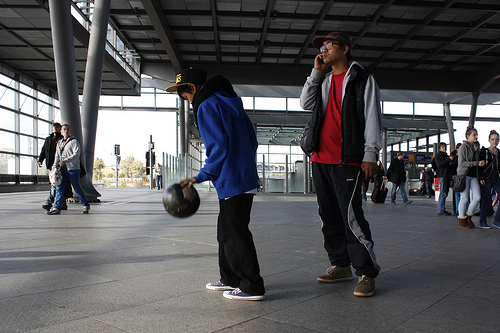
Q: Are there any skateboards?
A: No, there are no skateboards.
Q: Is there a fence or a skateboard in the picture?
A: No, there are no skateboards or fences.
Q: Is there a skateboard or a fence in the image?
A: No, there are no skateboards or fences.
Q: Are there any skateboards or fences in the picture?
A: No, there are no skateboards or fences.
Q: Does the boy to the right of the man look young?
A: Yes, the boy is young.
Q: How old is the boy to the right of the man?
A: The boy is young.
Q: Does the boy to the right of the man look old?
A: No, the boy is young.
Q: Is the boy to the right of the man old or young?
A: The boy is young.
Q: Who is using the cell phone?
A: The boy is using the cell phone.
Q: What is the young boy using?
A: The boy is using a mobile phone.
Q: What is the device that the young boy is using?
A: The device is a cell phone.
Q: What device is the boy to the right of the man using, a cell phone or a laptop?
A: The boy is using a cell phone.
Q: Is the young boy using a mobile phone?
A: Yes, the boy is using a mobile phone.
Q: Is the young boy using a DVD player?
A: No, the boy is using a mobile phone.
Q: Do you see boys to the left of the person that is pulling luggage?
A: Yes, there is a boy to the left of the person.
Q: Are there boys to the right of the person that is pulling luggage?
A: No, the boy is to the left of the person.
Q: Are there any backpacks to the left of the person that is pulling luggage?
A: No, there is a boy to the left of the person.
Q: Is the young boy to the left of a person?
A: Yes, the boy is to the left of a person.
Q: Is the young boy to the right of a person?
A: No, the boy is to the left of a person.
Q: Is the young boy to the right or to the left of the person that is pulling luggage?
A: The boy is to the left of the person.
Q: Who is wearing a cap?
A: The boy is wearing a cap.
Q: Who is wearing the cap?
A: The boy is wearing a cap.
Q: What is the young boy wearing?
A: The boy is wearing a cap.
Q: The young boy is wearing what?
A: The boy is wearing a cap.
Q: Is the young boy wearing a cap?
A: Yes, the boy is wearing a cap.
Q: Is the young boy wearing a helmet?
A: No, the boy is wearing a cap.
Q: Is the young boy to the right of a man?
A: Yes, the boy is to the right of a man.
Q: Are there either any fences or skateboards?
A: No, there are no fences or skateboards.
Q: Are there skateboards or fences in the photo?
A: No, there are no fences or skateboards.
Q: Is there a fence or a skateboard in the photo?
A: No, there are no fences or skateboards.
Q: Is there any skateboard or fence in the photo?
A: No, there are no fences or skateboards.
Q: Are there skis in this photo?
A: No, there are no skis.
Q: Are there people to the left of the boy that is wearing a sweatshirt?
A: No, the people are to the right of the boy.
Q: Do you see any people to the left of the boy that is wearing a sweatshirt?
A: No, the people are to the right of the boy.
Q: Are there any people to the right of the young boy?
A: Yes, there are people to the right of the boy.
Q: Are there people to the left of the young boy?
A: No, the people are to the right of the boy.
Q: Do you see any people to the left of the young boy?
A: No, the people are to the right of the boy.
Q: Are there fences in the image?
A: No, there are no fences.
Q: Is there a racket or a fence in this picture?
A: No, there are no fences or rackets.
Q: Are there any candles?
A: No, there are no candles.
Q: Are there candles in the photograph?
A: No, there are no candles.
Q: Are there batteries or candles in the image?
A: No, there are no candles or batteries.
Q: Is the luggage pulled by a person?
A: Yes, the luggage is pulled by a person.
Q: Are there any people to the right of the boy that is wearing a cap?
A: Yes, there is a person to the right of the boy.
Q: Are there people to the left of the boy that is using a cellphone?
A: No, the person is to the right of the boy.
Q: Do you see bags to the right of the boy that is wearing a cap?
A: No, there is a person to the right of the boy.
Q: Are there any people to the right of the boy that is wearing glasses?
A: Yes, there is a person to the right of the boy.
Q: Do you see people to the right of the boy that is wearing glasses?
A: Yes, there is a person to the right of the boy.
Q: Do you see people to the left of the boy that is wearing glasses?
A: No, the person is to the right of the boy.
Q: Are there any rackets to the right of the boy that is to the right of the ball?
A: No, there is a person to the right of the boy.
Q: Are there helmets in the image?
A: No, there are no helmets.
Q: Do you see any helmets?
A: No, there are no helmets.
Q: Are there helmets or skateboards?
A: No, there are no helmets or skateboards.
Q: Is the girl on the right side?
A: Yes, the girl is on the right of the image.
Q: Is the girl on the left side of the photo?
A: No, the girl is on the right of the image.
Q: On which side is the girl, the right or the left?
A: The girl is on the right of the image.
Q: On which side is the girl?
A: The girl is on the right of the image.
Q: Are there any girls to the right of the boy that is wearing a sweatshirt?
A: Yes, there is a girl to the right of the boy.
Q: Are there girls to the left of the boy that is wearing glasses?
A: No, the girl is to the right of the boy.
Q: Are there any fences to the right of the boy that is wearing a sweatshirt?
A: No, there is a girl to the right of the boy.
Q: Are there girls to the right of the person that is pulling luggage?
A: Yes, there is a girl to the right of the person.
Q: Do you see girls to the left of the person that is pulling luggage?
A: No, the girl is to the right of the person.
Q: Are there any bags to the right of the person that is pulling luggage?
A: No, there is a girl to the right of the person.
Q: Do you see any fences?
A: No, there are no fences.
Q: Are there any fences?
A: No, there are no fences.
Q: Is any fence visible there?
A: No, there are no fences.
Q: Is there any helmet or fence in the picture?
A: No, there are no fences or helmets.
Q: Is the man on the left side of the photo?
A: Yes, the man is on the left of the image.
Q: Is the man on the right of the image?
A: No, the man is on the left of the image.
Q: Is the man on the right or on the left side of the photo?
A: The man is on the left of the image.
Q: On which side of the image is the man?
A: The man is on the left of the image.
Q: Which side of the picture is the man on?
A: The man is on the left of the image.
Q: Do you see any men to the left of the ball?
A: Yes, there is a man to the left of the ball.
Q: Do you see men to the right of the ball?
A: No, the man is to the left of the ball.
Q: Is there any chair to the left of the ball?
A: No, there is a man to the left of the ball.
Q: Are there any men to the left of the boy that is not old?
A: Yes, there is a man to the left of the boy.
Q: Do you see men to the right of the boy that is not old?
A: No, the man is to the left of the boy.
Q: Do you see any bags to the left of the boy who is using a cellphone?
A: No, there is a man to the left of the boy.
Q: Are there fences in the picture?
A: No, there are no fences.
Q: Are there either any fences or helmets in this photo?
A: No, there are no fences or helmets.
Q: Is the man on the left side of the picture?
A: Yes, the man is on the left of the image.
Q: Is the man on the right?
A: No, the man is on the left of the image.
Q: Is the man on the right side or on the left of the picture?
A: The man is on the left of the image.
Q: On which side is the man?
A: The man is on the left of the image.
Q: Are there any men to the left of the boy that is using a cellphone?
A: Yes, there is a man to the left of the boy.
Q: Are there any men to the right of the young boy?
A: No, the man is to the left of the boy.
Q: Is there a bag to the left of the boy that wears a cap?
A: No, there is a man to the left of the boy.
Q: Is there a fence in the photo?
A: No, there are no fences.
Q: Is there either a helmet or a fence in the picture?
A: No, there are no fences or helmets.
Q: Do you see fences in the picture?
A: No, there are no fences.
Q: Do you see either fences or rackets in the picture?
A: No, there are no fences or rackets.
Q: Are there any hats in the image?
A: Yes, there is a hat.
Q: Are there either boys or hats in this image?
A: Yes, there is a hat.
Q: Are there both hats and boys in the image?
A: Yes, there are both a hat and a boy.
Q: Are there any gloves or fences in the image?
A: No, there are no fences or gloves.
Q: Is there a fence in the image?
A: No, there are no fences.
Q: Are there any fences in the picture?
A: No, there are no fences.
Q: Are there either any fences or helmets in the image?
A: No, there are no fences or helmets.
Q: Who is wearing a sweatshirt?
A: The boy is wearing a sweatshirt.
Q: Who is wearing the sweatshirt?
A: The boy is wearing a sweatshirt.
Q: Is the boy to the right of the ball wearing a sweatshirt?
A: Yes, the boy is wearing a sweatshirt.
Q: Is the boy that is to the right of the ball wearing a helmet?
A: No, the boy is wearing a sweatshirt.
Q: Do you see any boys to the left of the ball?
A: No, the boy is to the right of the ball.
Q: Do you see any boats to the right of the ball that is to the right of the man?
A: No, there is a boy to the right of the ball.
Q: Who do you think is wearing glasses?
A: The boy is wearing glasses.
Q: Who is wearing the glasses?
A: The boy is wearing glasses.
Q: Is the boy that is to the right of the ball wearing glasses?
A: Yes, the boy is wearing glasses.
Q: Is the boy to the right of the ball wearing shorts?
A: No, the boy is wearing glasses.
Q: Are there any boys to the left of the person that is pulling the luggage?
A: Yes, there is a boy to the left of the person.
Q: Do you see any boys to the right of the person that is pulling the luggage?
A: No, the boy is to the left of the person.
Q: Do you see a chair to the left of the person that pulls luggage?
A: No, there is a boy to the left of the person.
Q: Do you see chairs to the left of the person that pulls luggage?
A: No, there is a boy to the left of the person.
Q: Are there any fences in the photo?
A: No, there are no fences.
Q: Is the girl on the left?
A: No, the girl is on the right of the image.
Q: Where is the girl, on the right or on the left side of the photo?
A: The girl is on the right of the image.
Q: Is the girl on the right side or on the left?
A: The girl is on the right of the image.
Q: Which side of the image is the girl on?
A: The girl is on the right of the image.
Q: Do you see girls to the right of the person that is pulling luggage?
A: Yes, there is a girl to the right of the person.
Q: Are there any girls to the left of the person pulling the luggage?
A: No, the girl is to the right of the person.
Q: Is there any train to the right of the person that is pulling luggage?
A: No, there is a girl to the right of the person.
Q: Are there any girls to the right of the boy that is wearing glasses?
A: Yes, there is a girl to the right of the boy.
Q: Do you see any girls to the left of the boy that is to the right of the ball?
A: No, the girl is to the right of the boy.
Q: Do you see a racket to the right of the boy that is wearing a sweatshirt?
A: No, there is a girl to the right of the boy.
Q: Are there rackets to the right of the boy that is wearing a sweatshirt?
A: No, there is a girl to the right of the boy.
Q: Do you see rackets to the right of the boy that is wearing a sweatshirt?
A: No, there is a girl to the right of the boy.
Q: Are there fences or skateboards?
A: No, there are no fences or skateboards.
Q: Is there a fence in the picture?
A: No, there are no fences.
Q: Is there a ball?
A: Yes, there is a ball.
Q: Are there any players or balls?
A: Yes, there is a ball.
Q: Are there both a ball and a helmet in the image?
A: No, there is a ball but no helmets.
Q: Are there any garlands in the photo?
A: No, there are no garlands.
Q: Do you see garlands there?
A: No, there are no garlands.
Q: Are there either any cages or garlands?
A: No, there are no garlands or cages.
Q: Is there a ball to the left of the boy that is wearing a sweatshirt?
A: Yes, there is a ball to the left of the boy.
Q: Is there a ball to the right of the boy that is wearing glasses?
A: No, the ball is to the left of the boy.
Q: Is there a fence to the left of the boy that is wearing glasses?
A: No, there is a ball to the left of the boy.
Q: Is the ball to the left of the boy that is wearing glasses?
A: Yes, the ball is to the left of the boy.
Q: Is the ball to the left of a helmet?
A: No, the ball is to the left of the boy.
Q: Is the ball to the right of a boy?
A: No, the ball is to the left of a boy.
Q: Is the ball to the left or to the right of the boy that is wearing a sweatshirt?
A: The ball is to the left of the boy.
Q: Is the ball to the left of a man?
A: No, the ball is to the right of a man.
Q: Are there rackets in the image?
A: No, there are no rackets.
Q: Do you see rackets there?
A: No, there are no rackets.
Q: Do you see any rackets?
A: No, there are no rackets.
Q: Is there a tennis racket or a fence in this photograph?
A: No, there are no rackets or fences.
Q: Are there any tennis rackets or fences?
A: No, there are no tennis rackets or fences.